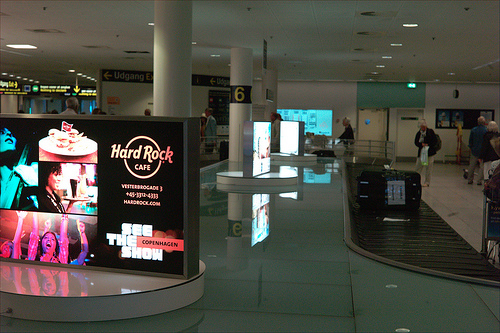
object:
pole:
[228, 46, 253, 163]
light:
[403, 23, 420, 29]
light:
[390, 43, 403, 47]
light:
[381, 55, 393, 59]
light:
[375, 65, 386, 68]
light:
[371, 72, 380, 75]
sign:
[242, 120, 272, 178]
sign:
[279, 121, 300, 156]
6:
[234, 87, 244, 101]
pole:
[151, 0, 194, 121]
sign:
[0, 119, 184, 278]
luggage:
[353, 169, 424, 216]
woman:
[476, 121, 499, 183]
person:
[414, 118, 437, 185]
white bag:
[420, 145, 430, 165]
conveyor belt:
[343, 158, 499, 285]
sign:
[252, 122, 277, 176]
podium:
[215, 171, 299, 193]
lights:
[370, 23, 419, 76]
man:
[466, 116, 488, 186]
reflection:
[227, 219, 243, 238]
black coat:
[415, 127, 437, 157]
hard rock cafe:
[106, 144, 176, 165]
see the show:
[105, 222, 179, 260]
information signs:
[0, 80, 95, 97]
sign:
[276, 108, 333, 137]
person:
[338, 116, 356, 156]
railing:
[324, 138, 396, 163]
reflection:
[250, 193, 271, 246]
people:
[201, 108, 218, 158]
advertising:
[252, 122, 271, 176]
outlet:
[4, 307, 17, 315]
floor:
[198, 142, 496, 328]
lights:
[6, 44, 98, 82]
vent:
[124, 50, 151, 54]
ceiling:
[3, 1, 499, 81]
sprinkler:
[459, 6, 475, 11]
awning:
[356, 82, 424, 108]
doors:
[358, 108, 422, 157]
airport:
[0, 0, 499, 331]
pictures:
[0, 123, 99, 268]